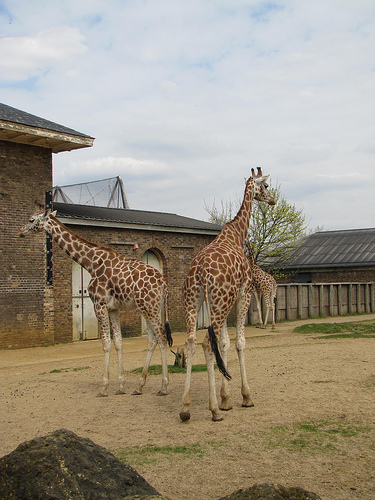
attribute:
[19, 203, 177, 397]
giraffe — standing, brown, white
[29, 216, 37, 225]
eye — black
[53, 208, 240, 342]
building — brick, brown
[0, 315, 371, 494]
dirt — brown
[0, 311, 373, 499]
ground — sandy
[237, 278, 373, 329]
fence — wooden, long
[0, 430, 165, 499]
boulder — black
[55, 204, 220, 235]
roof — black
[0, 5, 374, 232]
sky — cloudy, blue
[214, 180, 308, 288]
tree — green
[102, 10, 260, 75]
clouds — big, white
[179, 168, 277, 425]
giraffe — tall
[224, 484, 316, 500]
pile of dirt — small